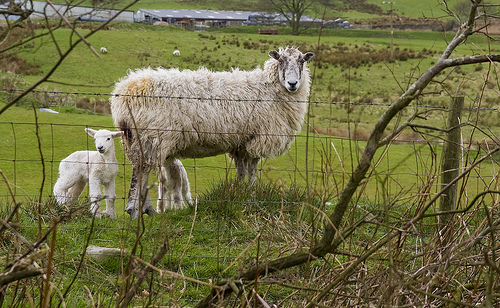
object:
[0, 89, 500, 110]
wire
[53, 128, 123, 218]
baby sheep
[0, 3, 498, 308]
field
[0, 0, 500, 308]
grass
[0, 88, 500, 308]
fence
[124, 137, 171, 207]
legs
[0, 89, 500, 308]
fencing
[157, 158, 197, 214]
lamb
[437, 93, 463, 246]
post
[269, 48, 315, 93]
head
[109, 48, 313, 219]
mother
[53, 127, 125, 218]
baby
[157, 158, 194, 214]
baby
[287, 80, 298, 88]
nose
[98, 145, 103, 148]
sheep's nose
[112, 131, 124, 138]
ear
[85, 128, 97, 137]
ear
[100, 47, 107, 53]
sheep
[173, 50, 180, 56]
sheep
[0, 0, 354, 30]
building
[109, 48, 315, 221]
sheep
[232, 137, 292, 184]
front legs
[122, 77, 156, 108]
dirty wool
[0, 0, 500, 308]
branches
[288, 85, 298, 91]
mouth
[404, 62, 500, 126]
bushes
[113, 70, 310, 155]
body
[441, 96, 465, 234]
stick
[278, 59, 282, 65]
eye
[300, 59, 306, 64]
eye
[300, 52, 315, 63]
ear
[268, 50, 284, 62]
ear